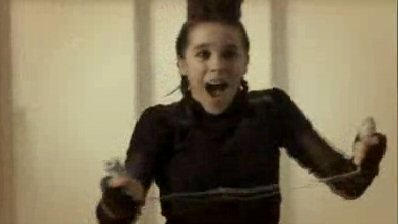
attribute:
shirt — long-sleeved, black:
[96, 85, 378, 220]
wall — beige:
[9, 11, 392, 216]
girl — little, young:
[94, 0, 385, 221]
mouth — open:
[200, 71, 231, 96]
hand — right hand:
[104, 172, 143, 203]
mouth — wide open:
[201, 70, 230, 101]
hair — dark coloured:
[173, 1, 254, 116]